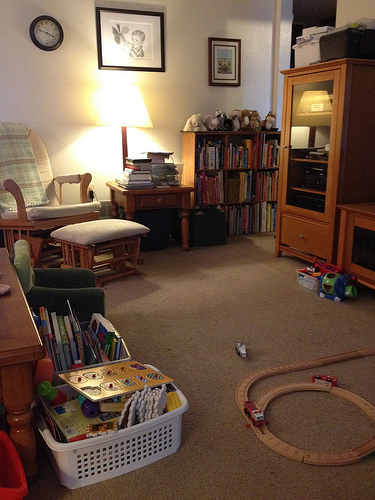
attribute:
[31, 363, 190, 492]
laundry basket — white, plastic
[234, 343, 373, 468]
track — brown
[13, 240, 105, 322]
kid's chair — small, green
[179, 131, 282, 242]
shelf — small, wooden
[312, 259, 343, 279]
toy car — red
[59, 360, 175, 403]
puzzle — wooden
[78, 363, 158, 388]
knobs — red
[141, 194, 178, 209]
drawer — brown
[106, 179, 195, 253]
end table — small, light brown, wooden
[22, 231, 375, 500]
floor — brown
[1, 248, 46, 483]
table — shiny, brown, wooden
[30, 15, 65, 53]
clock — black, white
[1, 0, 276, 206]
wall — white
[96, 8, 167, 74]
framed art — black, large, white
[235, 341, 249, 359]
toy — white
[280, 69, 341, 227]
door — brown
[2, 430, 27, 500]
bin — red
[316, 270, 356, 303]
child's toy — green, blue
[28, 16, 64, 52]
frame — black